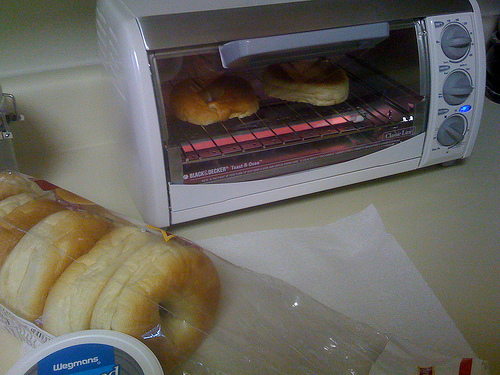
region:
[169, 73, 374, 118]
Toasted bagels in a toaster oven.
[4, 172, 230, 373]
Fresh bagels ready to be eaten or toasted.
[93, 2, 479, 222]
A toaster oven on a counter top.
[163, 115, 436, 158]
Red hot coils.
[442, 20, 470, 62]
A timer on the Toaster oven.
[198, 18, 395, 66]
A door handle.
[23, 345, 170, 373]
A Wegmans cover label.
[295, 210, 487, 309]
Waxed paper for bagel on counter top.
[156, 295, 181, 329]
Hole in the middle of bagel.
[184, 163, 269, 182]
Black and Decker label for Toaster oven.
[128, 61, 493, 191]
2 bagels are in the toaster oven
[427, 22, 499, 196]
The toaster oven has 3 knobs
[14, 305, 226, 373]
The brand name is wegmans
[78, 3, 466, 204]
The toaster oven is white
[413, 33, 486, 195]
The knobs are grey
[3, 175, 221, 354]
The bagels are in a plastic bag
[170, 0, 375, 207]
The bagels are toasting in the oven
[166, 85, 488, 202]
The light on the bottom is red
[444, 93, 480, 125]
The light is blue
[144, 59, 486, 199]
The bagels are on a rack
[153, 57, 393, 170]
The bagels are toasting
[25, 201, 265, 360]
The bagels are in a bag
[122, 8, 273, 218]
The toaster oven is white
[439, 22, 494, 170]
The knobs are gray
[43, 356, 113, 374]
This says wegmans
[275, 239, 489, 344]
The napkin is white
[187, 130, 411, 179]
The toasting part is red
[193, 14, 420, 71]
The handle is gray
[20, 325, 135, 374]
This is cream cheese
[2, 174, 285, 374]
There are 5 bagels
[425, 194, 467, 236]
part of a surface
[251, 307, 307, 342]
part of a polythene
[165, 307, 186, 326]
hole in a doughnut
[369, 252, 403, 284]
part of a paper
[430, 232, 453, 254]
part of a surface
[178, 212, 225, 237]
edge of a microwave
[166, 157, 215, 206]
part of a microwave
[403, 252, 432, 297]
edge of a tissue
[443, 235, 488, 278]
part of a surface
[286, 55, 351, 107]
part of a microwave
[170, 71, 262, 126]
bagel top toasting in oven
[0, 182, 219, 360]
bag of fresh bagels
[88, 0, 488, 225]
Black & Decker brand toaster oven.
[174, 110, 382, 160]
toaster oven heating element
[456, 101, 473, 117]
toaster oven power on indicator light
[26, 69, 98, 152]
beige counter top backsplash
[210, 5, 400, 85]
grey metal handle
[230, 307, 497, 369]
empty space in plastic bag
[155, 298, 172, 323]
hole in center of bagel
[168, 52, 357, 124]
a bagel split in half